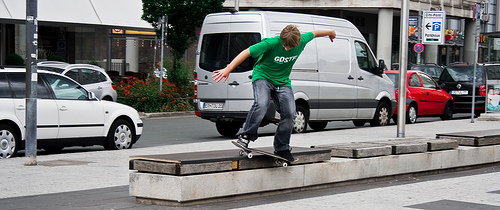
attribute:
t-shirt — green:
[254, 43, 311, 83]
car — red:
[388, 66, 456, 122]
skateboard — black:
[231, 140, 291, 170]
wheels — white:
[236, 151, 242, 155]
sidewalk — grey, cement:
[0, 116, 498, 200]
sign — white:
[422, 11, 446, 44]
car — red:
[373, 42, 451, 137]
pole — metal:
[16, 3, 44, 168]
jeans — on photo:
[238, 79, 299, 159]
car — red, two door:
[386, 71, 453, 118]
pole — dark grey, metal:
[23, 3, 43, 167]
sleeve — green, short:
[248, 41, 269, 60]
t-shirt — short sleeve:
[264, 37, 296, 88]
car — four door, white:
[1, 67, 143, 159]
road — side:
[147, 110, 198, 136]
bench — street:
[142, 164, 321, 191]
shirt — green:
[259, 32, 293, 84]